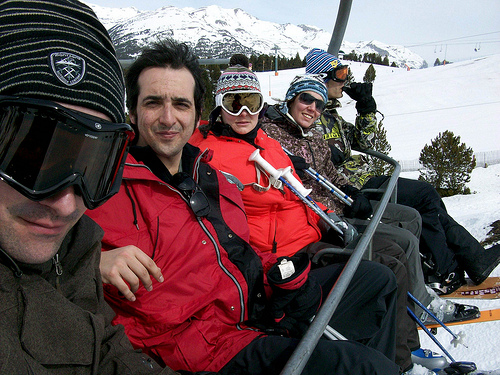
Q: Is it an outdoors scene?
A: Yes, it is outdoors.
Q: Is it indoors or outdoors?
A: It is outdoors.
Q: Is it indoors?
A: No, it is outdoors.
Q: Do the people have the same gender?
A: No, they are both male and female.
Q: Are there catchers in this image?
A: No, there are no catchers.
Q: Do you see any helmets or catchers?
A: No, there are no catchers or helmets.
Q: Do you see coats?
A: Yes, there is a coat.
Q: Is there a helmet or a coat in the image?
A: Yes, there is a coat.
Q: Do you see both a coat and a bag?
A: No, there is a coat but no bags.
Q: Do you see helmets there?
A: No, there are no helmets.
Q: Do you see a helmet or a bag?
A: No, there are no helmets or bags.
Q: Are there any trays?
A: No, there are no trays.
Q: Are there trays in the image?
A: No, there are no trays.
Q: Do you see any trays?
A: No, there are no trays.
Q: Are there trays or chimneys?
A: No, there are no trays or chimneys.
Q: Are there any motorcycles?
A: No, there are no motorcycles.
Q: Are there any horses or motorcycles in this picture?
A: No, there are no motorcycles or horses.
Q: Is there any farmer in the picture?
A: No, there are no farmers.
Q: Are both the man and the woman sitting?
A: Yes, both the man and the woman are sitting.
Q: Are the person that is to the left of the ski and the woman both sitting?
A: Yes, both the man and the woman are sitting.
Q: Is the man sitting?
A: Yes, the man is sitting.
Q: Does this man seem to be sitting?
A: Yes, the man is sitting.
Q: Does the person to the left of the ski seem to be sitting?
A: Yes, the man is sitting.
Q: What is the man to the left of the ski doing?
A: The man is sitting.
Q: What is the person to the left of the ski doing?
A: The man is sitting.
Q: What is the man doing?
A: The man is sitting.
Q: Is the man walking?
A: No, the man is sitting.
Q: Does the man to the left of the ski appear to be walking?
A: No, the man is sitting.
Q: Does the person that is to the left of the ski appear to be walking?
A: No, the man is sitting.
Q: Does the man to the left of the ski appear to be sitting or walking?
A: The man is sitting.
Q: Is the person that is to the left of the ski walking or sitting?
A: The man is sitting.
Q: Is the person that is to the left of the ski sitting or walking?
A: The man is sitting.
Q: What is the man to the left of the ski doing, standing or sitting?
A: The man is sitting.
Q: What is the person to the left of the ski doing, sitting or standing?
A: The man is sitting.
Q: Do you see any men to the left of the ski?
A: Yes, there is a man to the left of the ski.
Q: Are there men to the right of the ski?
A: No, the man is to the left of the ski.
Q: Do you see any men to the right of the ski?
A: No, the man is to the left of the ski.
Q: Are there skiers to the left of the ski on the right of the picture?
A: No, there is a man to the left of the ski.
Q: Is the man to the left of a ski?
A: Yes, the man is to the left of a ski.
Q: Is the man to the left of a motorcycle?
A: No, the man is to the left of a ski.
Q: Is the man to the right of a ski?
A: No, the man is to the left of a ski.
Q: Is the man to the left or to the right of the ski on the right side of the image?
A: The man is to the left of the ski.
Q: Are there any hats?
A: Yes, there is a hat.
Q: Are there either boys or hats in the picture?
A: Yes, there is a hat.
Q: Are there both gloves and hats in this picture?
A: Yes, there are both a hat and gloves.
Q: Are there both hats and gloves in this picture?
A: Yes, there are both a hat and gloves.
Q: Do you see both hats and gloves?
A: Yes, there are both a hat and gloves.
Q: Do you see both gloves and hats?
A: Yes, there are both a hat and gloves.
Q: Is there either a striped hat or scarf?
A: Yes, there is a striped hat.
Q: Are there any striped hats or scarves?
A: Yes, there is a striped hat.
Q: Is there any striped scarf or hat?
A: Yes, there is a striped hat.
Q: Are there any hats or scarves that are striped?
A: Yes, the hat is striped.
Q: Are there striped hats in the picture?
A: Yes, there is a striped hat.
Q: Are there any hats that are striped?
A: Yes, there is a hat that is striped.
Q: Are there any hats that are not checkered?
A: Yes, there is a striped hat.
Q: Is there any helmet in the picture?
A: No, there are no helmets.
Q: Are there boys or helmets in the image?
A: No, there are no helmets or boys.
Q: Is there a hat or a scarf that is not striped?
A: No, there is a hat but it is striped.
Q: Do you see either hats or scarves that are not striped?
A: No, there is a hat but it is striped.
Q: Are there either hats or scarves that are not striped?
A: No, there is a hat but it is striped.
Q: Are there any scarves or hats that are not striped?
A: No, there is a hat but it is striped.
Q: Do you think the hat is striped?
A: Yes, the hat is striped.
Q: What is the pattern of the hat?
A: The hat is striped.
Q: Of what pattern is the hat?
A: The hat is striped.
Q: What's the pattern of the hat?
A: The hat is striped.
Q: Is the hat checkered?
A: No, the hat is striped.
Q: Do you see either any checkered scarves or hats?
A: No, there is a hat but it is striped.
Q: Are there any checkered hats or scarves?
A: No, there is a hat but it is striped.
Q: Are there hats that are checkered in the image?
A: No, there is a hat but it is striped.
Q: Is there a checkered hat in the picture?
A: No, there is a hat but it is striped.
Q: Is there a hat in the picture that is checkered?
A: No, there is a hat but it is striped.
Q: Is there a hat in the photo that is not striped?
A: No, there is a hat but it is striped.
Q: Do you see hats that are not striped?
A: No, there is a hat but it is striped.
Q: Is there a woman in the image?
A: Yes, there is a woman.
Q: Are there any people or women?
A: Yes, there is a woman.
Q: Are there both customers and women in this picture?
A: No, there is a woman but no customers.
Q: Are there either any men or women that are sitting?
A: Yes, the woman is sitting.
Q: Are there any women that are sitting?
A: Yes, there is a woman that is sitting.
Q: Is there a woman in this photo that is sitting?
A: Yes, there is a woman that is sitting.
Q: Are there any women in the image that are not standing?
A: Yes, there is a woman that is sitting.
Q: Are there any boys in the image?
A: No, there are no boys.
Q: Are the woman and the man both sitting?
A: Yes, both the woman and the man are sitting.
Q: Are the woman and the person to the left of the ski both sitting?
A: Yes, both the woman and the man are sitting.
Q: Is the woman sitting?
A: Yes, the woman is sitting.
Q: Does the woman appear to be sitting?
A: Yes, the woman is sitting.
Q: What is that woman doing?
A: The woman is sitting.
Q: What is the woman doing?
A: The woman is sitting.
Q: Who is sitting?
A: The woman is sitting.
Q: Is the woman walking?
A: No, the woman is sitting.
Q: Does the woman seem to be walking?
A: No, the woman is sitting.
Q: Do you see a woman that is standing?
A: No, there is a woman but she is sitting.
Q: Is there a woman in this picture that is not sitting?
A: No, there is a woman but she is sitting.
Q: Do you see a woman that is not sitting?
A: No, there is a woman but she is sitting.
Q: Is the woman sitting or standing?
A: The woman is sitting.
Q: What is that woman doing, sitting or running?
A: The woman is sitting.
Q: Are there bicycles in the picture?
A: No, there are no bicycles.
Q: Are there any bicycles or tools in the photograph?
A: No, there are no bicycles or tools.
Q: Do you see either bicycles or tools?
A: No, there are no bicycles or tools.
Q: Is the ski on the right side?
A: Yes, the ski is on the right of the image.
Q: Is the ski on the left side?
A: No, the ski is on the right of the image.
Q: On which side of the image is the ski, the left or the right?
A: The ski is on the right of the image.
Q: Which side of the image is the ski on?
A: The ski is on the right of the image.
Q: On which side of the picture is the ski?
A: The ski is on the right of the image.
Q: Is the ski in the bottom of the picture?
A: Yes, the ski is in the bottom of the image.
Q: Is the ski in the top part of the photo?
A: No, the ski is in the bottom of the image.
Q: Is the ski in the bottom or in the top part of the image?
A: The ski is in the bottom of the image.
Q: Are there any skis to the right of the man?
A: Yes, there is a ski to the right of the man.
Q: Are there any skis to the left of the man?
A: No, the ski is to the right of the man.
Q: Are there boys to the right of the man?
A: No, there is a ski to the right of the man.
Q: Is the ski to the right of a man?
A: Yes, the ski is to the right of a man.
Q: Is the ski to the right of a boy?
A: No, the ski is to the right of a man.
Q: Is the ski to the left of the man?
A: No, the ski is to the right of the man.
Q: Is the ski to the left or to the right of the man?
A: The ski is to the right of the man.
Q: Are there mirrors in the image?
A: No, there are no mirrors.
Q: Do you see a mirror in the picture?
A: No, there are no mirrors.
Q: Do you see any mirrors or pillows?
A: No, there are no mirrors or pillows.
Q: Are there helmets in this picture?
A: No, there are no helmets.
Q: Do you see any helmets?
A: No, there are no helmets.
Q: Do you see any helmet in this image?
A: No, there are no helmets.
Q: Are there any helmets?
A: No, there are no helmets.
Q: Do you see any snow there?
A: Yes, there is snow.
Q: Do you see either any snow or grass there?
A: Yes, there is snow.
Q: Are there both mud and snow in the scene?
A: No, there is snow but no mud.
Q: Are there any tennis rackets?
A: No, there are no tennis rackets.